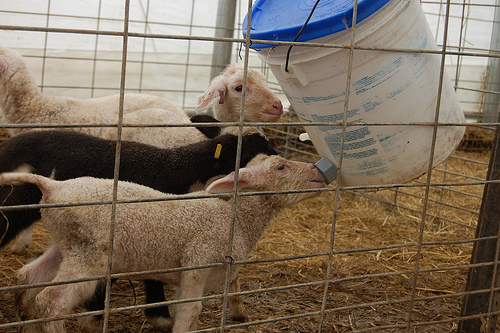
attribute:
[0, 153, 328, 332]
sheep — drinking, here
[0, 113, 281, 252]
sheep — black, brown, here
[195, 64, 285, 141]
sheep — here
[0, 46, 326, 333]
lambs — black, white, babies, facing right, group, feeding, grouped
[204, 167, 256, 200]
ear — pushed back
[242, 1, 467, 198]
container — large, feeding, white, hanging, tilted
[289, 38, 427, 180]
writing — blue, small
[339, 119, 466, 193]
smudges — dirt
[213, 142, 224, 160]
tag — yellow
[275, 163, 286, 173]
eye — black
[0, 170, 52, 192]
tail — fluffy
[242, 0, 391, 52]
lid — blue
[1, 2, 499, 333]
bars — metal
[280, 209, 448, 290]
hay — yellow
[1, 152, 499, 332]
floor — covered